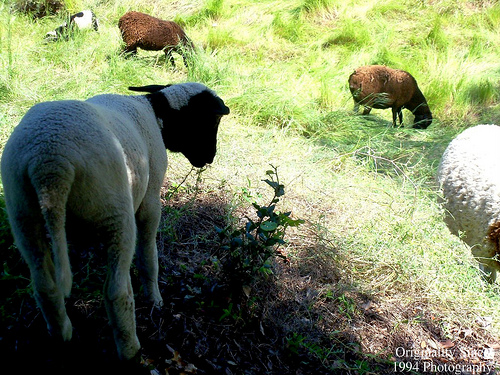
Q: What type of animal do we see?
A: Sheep.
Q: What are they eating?
A: Grass.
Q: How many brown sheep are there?
A: 2.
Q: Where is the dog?
A: There is no dog.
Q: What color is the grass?
A: Green.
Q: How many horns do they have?
A: None.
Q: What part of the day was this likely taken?
A: Daytime.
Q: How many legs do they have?
A: 4.